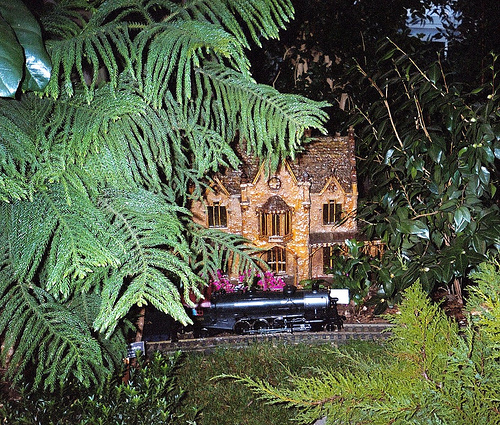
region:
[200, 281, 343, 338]
a toy train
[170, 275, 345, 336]
the train is black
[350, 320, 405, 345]
the toy train tracks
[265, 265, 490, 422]
the trees in the corner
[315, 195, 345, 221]
the window on the second story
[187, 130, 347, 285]
a brown house by the tracks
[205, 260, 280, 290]
pink flowers behind the train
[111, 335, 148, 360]
a sign on the palm tree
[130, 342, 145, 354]
a skull on the palm tree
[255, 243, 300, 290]
archway on the house.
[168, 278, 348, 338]
a toy train and track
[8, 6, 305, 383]
boughs of norfolk island pine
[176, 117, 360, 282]
a tiny brick mansion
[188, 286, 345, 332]
a black steam engine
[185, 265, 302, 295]
toy pink flowers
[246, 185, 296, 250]
a bowed unstairs window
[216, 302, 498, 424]
fernlike evergreen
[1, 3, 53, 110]
large smooth leaves reflect light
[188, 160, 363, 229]
three gables on front of mansion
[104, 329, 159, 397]
a small sign in the greenery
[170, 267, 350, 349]
The train is a model train.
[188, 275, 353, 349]
The train is black.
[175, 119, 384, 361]
The train rides past a model house.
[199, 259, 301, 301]
Pink flowers are in front of the house.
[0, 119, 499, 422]
Plants surround the house.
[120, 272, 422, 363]
The train rides a track.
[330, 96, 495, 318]
The plant has leaves.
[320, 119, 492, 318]
The leaves are green.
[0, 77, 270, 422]
The plant partially hides the track.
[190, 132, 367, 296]
The house has windows.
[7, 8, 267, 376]
A green fern type plant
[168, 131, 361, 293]
A building behind the plants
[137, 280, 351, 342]
A model train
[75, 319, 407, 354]
Model train tracks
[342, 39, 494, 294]
A green plant near the train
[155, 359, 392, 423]
The grass is cut short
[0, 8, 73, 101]
Plastic looking leaves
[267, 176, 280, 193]
A clock on the building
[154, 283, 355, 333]
The train is black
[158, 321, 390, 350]
Train tracks under the train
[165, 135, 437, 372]
Model size house by a train.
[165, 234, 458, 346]
Train by a house.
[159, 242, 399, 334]
Model train by a house.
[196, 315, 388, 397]
Grass on the ground.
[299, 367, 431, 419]
Trees in the background.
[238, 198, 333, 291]
Windows on the house.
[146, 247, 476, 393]
Train on the tracks.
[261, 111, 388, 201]
Roof on the house.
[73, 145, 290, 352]
Leaves on the tree.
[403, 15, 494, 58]
Sky in the background.